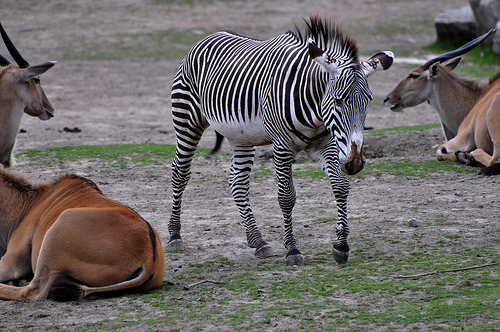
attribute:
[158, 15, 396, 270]
zebra — walking, black, white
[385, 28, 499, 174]
giselle — laying down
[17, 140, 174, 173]
grass — patch, green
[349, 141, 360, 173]
nose — brown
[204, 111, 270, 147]
stomach — white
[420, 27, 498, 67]
horns — grey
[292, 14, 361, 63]
mane — black, white, bushy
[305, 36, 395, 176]
head — down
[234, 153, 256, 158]
stripe — black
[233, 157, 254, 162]
stripe — white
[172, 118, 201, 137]
stripe — black, white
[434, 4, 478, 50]
rock — large, grey, gray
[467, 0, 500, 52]
rock — grey, large, gray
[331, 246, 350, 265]
hoof — grey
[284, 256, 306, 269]
hoof — grey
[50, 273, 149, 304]
tail — brown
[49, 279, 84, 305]
end — bushy, black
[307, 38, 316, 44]
tip — white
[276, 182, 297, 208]
knee — knobby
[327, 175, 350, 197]
knee — knobby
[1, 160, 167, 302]
animal — brown, sitting, large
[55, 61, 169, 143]
patch — grey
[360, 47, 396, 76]
ear — black, white